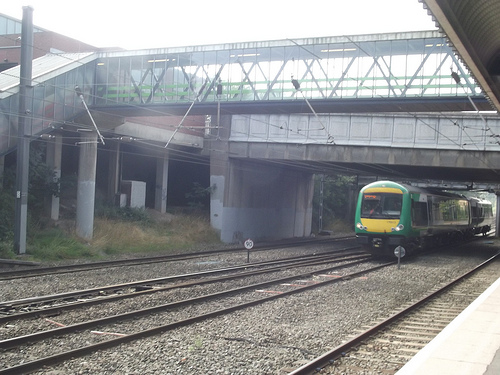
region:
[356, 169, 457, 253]
the train is green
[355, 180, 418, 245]
the train is yellow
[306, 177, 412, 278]
the train is on the tracks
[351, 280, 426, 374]
the tracks are beside the train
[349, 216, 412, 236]
the train has headlights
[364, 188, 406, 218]
the train has a windshield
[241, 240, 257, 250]
the number is black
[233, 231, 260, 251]
the sign is round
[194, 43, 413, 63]
the walkway is lit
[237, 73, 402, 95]
the railing is green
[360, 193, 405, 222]
The windshield of a train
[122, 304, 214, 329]
Train tracks three of four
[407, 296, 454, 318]
Train tracks four of four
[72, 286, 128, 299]
Train tracks two of four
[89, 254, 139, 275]
Train tracks one of four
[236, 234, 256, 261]
A railroad sign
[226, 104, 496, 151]
A sky-way crossing over the four railroad tracks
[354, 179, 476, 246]
A green and yellow train on tracks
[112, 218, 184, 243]
A grassy hillside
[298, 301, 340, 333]
Gravel and river rock between the third and fourth tracks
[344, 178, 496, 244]
Green and yellow train on rails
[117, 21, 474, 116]
Metal walkway with green railing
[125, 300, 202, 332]
Metal train tracks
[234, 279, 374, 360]
Gravel between two train tracks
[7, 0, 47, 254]
Tall metal pole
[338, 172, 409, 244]
Green and yellow face of a train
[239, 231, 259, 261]
Small metal sign with a white face and black lettering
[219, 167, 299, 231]
Blue and gray wall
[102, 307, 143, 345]
Two rails of a train track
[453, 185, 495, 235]
Second car of a train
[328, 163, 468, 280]
The train is on the tracks.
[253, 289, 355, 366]
Gravel in between the tracks.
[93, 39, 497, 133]
A walkway above the tracks.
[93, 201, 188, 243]
Green grass on the ground.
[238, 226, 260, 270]
Sticks with numbers on it.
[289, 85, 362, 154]
Wires hanging from the top of tunnel.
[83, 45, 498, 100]
Walkway over tunnel.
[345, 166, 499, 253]
Train is going through underpass.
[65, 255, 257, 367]
Tracks on the ground.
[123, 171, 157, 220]
A electrical box on the grass.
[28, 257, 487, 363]
There are multiple train tracks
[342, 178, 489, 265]
Yellow and green train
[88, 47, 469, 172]
A bridge over the tracks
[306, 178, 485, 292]
The train is under the bridge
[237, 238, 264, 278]
White round sign next to the track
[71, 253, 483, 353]
Gravel under the tracks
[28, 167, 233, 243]
Grass under the pillars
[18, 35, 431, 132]
The walkway has glass windows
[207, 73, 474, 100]
There are people walking over the bridge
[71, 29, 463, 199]
The wires above the train are grey